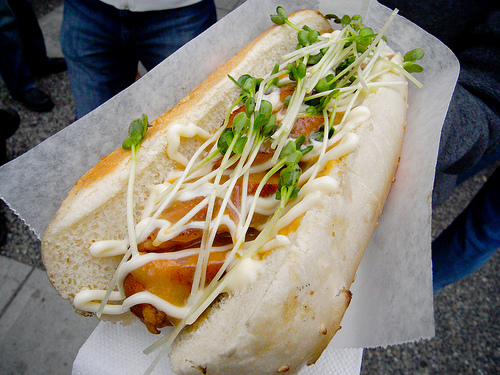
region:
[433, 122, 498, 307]
human legs wearing blue jeans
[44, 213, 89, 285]
well textured crumb of bread bun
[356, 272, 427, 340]
white flimsy wax paper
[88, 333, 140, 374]
thinly meshed paper towel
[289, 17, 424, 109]
grouping of vegetable sprouts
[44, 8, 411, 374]
hot dog on toasted bun covered in cheese and sprouts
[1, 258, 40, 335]
cement walk way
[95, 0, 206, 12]
hem of white shirt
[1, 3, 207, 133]
multiple pairs of human legs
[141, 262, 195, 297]
melted orange cheese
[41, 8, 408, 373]
a hot dog on a paper wrapper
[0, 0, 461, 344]
a white paper wrapper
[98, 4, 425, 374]
alfalfa on a hot dog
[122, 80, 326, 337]
a wiener with ketchup and mustard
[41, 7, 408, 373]
a hot dog bun with alfalfa toppings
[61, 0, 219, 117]
a man wearing jeans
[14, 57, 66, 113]
a man wearing black shoes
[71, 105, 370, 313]
mayonnaise on a hot dog bun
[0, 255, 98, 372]
wooden planks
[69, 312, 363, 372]
a white paper towel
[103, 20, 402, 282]
hot dog with many toppings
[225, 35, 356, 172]
green onions on the hotdog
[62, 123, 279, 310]
mayo on the hotdog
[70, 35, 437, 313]
hotdog is on a wrapper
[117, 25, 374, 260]
hotdog is in a bun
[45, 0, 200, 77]
the jeans are blue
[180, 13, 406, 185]
the onions are white and green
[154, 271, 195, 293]
the hotdog has cheese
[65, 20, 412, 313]
the hotdog looks delicious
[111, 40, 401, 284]
the hotdog has many onions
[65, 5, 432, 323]
hot dog covered in food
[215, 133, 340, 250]
white topping on hot dog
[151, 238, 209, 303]
yellow topping on hot dog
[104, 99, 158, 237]
green vegetable on hot dog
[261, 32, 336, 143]
white sprouts on hot dog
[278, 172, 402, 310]
white part of bun of dog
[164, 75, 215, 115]
yellow portion of bun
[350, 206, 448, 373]
white paper holder for food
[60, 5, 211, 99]
blue jeans on legs of person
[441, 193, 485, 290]
blue jeans on legs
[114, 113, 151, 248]
a piece of garnish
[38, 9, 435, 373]
a hot dog with garnish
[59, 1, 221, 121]
a person wearing jeans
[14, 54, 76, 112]
a person wearing black boots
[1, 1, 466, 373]
a hot dog on a white sheet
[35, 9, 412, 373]
a toasted hot dog bun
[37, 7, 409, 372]
a cooked hot dog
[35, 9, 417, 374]
a hot dog with dressing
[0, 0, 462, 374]
a white paper holding a hot dog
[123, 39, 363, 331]
a hot dog in a bun